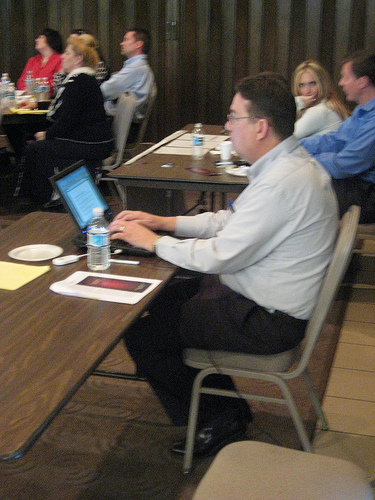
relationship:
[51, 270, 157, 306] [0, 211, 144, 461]
paper on table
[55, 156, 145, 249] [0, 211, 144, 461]
laptop on table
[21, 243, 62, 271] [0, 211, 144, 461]
plate on table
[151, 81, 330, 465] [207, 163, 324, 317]
man wears shirt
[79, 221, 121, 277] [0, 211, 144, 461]
bottle on table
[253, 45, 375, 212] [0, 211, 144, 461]
people at table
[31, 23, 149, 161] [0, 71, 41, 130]
people at table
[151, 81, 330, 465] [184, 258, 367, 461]
man sits in chair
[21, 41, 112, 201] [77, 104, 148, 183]
woman sits in chair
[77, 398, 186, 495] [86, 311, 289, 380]
carpet on floor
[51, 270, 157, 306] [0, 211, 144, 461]
paper sits on table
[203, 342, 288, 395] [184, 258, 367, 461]
cushion on chair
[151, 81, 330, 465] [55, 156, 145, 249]
man works on laptop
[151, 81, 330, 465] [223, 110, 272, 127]
man wears eyeglasses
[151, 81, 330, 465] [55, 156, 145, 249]
man types on laptop